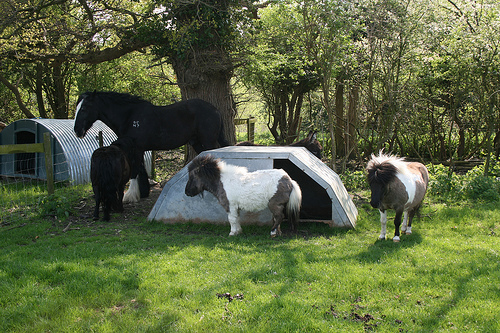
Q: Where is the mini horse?
A: In a field.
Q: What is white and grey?
A: Mini horse.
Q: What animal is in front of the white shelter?
A: Pony.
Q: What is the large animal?
A: Horse.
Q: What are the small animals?
A: Ponies.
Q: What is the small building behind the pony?
A: A shelter.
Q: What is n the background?
A: Trees.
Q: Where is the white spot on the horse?
A: Face.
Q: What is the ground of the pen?
A: Grass.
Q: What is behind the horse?
A: Tree.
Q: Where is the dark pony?
A: By the horse.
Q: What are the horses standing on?
A: Grass.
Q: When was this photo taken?
A: During the daytime.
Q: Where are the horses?
A: Standing on the grass.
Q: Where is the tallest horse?
A: Next to the tree trunk.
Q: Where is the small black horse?
A: Near the large black horse.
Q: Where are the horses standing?
A: Near the trees.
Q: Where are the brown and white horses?
A: On the right side.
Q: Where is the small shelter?
A: Behind the brown and white horse.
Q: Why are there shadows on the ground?
A: From the sun shining on the trees.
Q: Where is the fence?
A: Near the black horses.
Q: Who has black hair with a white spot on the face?
A: The tallest horse.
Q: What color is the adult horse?
A: Black.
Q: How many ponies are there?
A: 3.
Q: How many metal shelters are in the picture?
A: 2.